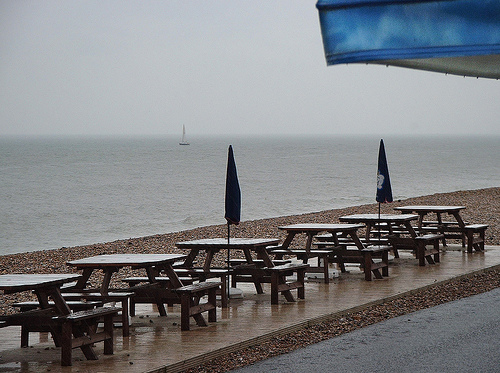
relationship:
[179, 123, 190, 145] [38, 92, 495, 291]
boat on water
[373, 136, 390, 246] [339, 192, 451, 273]
umbrella on table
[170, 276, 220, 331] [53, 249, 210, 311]
bench behind table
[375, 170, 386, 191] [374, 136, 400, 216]
logo on umbrella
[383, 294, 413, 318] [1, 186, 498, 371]
gravel between raised area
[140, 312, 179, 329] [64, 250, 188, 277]
pinecones underneath table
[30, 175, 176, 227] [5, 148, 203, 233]
ripples in water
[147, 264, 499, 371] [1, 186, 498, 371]
aggregate on raised area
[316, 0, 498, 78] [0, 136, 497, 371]
fabric canopy over water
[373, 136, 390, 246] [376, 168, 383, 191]
umbrella has logo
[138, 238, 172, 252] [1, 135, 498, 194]
gravel by water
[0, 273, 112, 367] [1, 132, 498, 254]
table by water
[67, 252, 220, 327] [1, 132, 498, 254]
table by water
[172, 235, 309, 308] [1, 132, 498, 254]
table by water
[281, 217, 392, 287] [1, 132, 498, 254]
table by water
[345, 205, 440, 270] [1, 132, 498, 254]
table by water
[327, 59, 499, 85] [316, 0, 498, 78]
droplets on fabric canopy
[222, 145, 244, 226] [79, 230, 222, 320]
umbrella on table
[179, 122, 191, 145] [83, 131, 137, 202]
boat in ocean